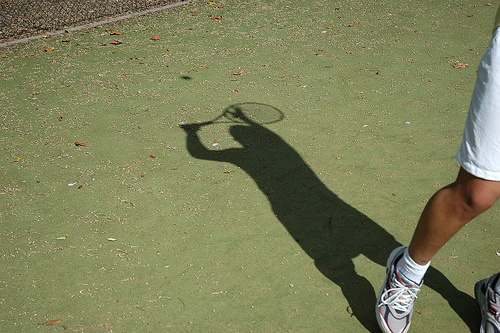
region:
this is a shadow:
[174, 73, 474, 330]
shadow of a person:
[152, 86, 497, 323]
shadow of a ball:
[156, 60, 207, 94]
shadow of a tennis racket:
[165, 88, 297, 143]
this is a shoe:
[376, 199, 437, 331]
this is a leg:
[360, 28, 499, 330]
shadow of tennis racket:
[183, 88, 293, 148]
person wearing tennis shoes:
[368, 226, 441, 328]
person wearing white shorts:
[452, 22, 497, 199]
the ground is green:
[26, 16, 493, 330]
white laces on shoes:
[373, 271, 420, 313]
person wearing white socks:
[382, 208, 442, 301]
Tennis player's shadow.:
[173, 93, 486, 332]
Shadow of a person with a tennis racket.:
[175, 97, 486, 332]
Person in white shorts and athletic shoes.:
[369, 3, 499, 331]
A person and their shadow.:
[181, 1, 497, 331]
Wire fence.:
[1, 0, 207, 51]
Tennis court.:
[2, 0, 499, 332]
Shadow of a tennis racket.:
[179, 93, 286, 139]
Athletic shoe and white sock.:
[373, 242, 428, 332]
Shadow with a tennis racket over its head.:
[178, 97, 485, 331]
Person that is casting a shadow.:
[370, 3, 497, 330]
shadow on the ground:
[192, 63, 397, 329]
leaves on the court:
[39, 28, 204, 78]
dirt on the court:
[18, 145, 145, 315]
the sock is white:
[400, 247, 427, 290]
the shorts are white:
[464, 91, 496, 183]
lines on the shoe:
[382, 305, 407, 329]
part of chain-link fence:
[0, 0, 192, 47]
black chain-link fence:
[0, 0, 192, 50]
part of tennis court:
[0, 0, 499, 332]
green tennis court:
[3, 0, 497, 330]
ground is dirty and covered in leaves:
[2, 0, 497, 330]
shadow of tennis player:
[182, 100, 477, 330]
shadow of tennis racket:
[193, 99, 284, 127]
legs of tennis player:
[376, 158, 498, 331]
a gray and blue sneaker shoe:
[376, 245, 418, 330]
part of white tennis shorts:
[459, 20, 497, 180]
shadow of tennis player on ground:
[170, 83, 487, 332]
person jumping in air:
[366, 3, 497, 330]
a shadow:
[193, 102, 368, 241]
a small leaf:
[61, 130, 99, 160]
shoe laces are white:
[379, 285, 406, 310]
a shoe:
[377, 298, 420, 321]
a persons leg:
[420, 190, 461, 250]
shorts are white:
[461, 119, 496, 171]